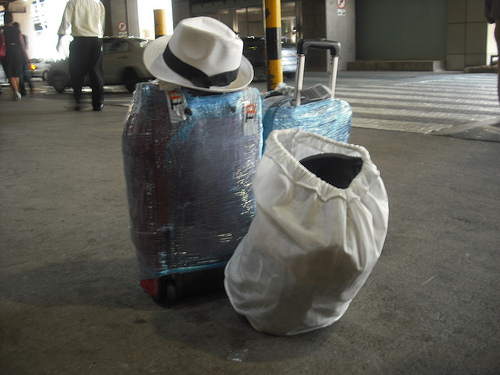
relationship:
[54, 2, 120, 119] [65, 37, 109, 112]
man has pants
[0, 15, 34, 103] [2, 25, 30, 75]
woman wearing dress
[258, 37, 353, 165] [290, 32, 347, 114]
suitcase has handle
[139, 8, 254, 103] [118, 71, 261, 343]
hat on suitcase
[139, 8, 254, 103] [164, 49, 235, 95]
hat has band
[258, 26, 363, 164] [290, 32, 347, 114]
suitcase has handle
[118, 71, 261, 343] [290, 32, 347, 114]
suitcase has handle